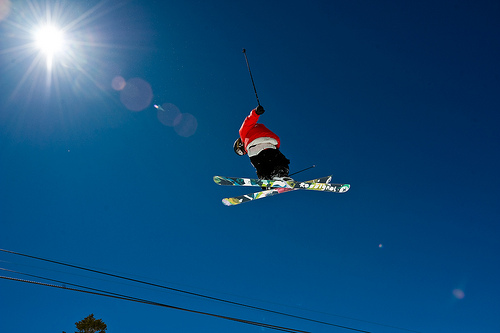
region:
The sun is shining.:
[0, 2, 130, 107]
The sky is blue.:
[325, 43, 475, 160]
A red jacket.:
[230, 113, 283, 150]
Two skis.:
[196, 170, 360, 224]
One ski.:
[205, 175, 365, 190]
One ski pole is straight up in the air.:
[230, 40, 275, 110]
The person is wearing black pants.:
[243, 145, 304, 178]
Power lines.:
[5, 236, 427, 328]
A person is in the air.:
[205, 48, 370, 233]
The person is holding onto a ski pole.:
[290, 156, 330, 186]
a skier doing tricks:
[154, 50, 389, 281]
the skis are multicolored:
[203, 149, 368, 246]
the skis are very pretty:
[203, 176, 365, 226]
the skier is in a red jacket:
[177, 83, 349, 268]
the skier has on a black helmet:
[212, 118, 248, 165]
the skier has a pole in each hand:
[163, 41, 340, 236]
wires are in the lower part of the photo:
[11, 240, 203, 327]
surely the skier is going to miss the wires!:
[34, 50, 412, 323]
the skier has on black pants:
[231, 145, 303, 195]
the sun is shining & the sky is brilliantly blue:
[19, 8, 499, 275]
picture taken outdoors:
[56, 45, 420, 321]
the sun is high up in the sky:
[83, 43, 461, 301]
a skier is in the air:
[177, 30, 313, 331]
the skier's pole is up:
[218, 47, 289, 92]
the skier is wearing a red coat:
[117, 57, 439, 202]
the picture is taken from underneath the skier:
[93, 30, 423, 206]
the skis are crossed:
[245, 181, 360, 245]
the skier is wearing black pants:
[213, 167, 353, 223]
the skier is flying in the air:
[196, 106, 442, 266]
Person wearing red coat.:
[228, 112, 270, 162]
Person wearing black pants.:
[249, 152, 282, 174]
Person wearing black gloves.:
[243, 105, 293, 117]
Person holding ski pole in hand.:
[243, 62, 295, 124]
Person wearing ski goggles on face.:
[222, 132, 253, 170]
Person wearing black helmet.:
[213, 130, 256, 191]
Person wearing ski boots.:
[263, 169, 320, 198]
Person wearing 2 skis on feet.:
[216, 159, 408, 241]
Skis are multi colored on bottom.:
[223, 147, 385, 233]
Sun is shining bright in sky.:
[38, 25, 127, 151]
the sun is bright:
[4, 0, 110, 105]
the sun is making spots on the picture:
[101, 67, 465, 300]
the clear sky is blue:
[0, 1, 499, 331]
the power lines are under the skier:
[0, 246, 370, 331]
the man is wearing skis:
[209, 165, 356, 214]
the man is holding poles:
[238, 45, 318, 182]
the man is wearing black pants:
[243, 144, 292, 181]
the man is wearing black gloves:
[253, 100, 264, 117]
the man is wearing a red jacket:
[236, 105, 281, 152]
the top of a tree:
[68, 310, 108, 331]